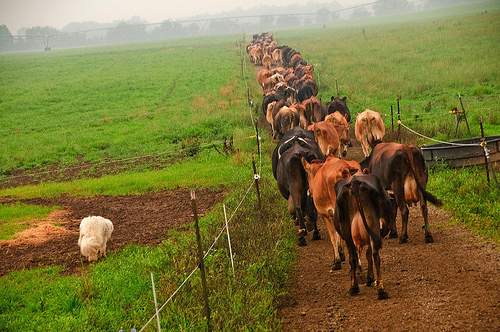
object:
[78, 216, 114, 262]
dog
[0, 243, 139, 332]
grass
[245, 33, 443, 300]
herd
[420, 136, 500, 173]
tub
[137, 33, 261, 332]
fence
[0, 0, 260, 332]
field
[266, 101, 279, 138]
cow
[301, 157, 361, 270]
cow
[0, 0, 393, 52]
cropdusters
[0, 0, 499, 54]
fog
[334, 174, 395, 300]
cow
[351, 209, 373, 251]
udder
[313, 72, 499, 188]
fence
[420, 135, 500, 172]
posts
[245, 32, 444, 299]
trail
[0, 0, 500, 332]
field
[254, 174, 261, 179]
sheep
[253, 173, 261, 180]
sheep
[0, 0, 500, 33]
distance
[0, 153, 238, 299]
mud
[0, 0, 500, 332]
grass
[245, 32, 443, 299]
line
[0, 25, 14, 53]
trees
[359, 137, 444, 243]
cow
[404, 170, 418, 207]
udder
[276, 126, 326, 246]
cow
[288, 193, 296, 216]
udder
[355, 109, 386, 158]
cow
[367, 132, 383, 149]
udder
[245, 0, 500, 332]
cow path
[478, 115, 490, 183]
fences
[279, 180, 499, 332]
cow path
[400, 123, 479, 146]
rope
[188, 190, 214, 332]
post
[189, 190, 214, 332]
fence post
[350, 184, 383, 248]
tail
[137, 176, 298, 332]
dirt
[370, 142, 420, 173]
dirt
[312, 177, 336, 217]
stomach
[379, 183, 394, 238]
stomach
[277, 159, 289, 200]
stomach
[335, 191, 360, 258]
thigh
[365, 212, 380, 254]
thigh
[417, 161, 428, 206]
thigh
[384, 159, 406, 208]
thigh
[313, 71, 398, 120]
rope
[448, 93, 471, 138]
posts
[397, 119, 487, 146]
yellow fasteners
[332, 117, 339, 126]
tail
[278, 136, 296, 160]
stripes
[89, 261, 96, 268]
mysterious thing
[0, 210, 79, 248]
sand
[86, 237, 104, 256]
ear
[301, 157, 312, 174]
ear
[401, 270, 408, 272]
'turkerworker